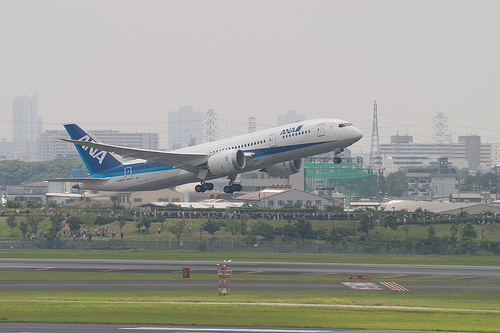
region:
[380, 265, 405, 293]
part of a run way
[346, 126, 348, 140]
tip of a plane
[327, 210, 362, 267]
part of a forest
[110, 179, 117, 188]
bottom of a plane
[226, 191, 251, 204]
part of a wheel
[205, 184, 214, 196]
edge of a wheel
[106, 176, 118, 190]
back of a plane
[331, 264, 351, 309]
part of a run way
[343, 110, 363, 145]
tip of a plane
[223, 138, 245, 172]
part of an engine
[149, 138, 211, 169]
edge of a wing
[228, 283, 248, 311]
part of a field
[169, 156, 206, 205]
part of a wheel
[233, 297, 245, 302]
part of a ground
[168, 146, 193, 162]
edge of a wing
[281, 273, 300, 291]
part of a runway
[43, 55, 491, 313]
Jet plane taking off from airport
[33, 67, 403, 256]
Jet plane taking flight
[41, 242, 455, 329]
Runway at airport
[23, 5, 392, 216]
Overcast sky that plane is going into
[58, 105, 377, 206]
Jet plane is white with light and dark blue stripes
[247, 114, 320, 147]
Plane is from AVA airline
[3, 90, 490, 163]
Large buildings in the distance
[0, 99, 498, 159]
Power lines in the distance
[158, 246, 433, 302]
Runway at airport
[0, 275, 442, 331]
Green grass between runways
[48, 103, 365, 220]
Plane in the air.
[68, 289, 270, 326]
The grass is green.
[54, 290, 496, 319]
Pathway in the grass.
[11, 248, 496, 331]
There are three lanes.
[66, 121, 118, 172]
ANA on the plane.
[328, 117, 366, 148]
Cockpit of the plane.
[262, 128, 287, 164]
The door is closed.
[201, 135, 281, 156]
Windows on the plane.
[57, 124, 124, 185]
The tail is mostly blue.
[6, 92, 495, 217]
Buildings in the background.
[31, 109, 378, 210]
an airplane is taking off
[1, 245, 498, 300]
landing lanes below a plane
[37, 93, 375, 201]
plane color is white and blue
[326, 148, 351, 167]
front wheel of plane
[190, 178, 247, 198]
front wheels of plane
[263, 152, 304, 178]
right engine of plane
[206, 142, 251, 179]
left engine of plane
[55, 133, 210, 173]
white wing of plane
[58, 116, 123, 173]
vertical stabilizer is blue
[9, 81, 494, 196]
a city behind a plane